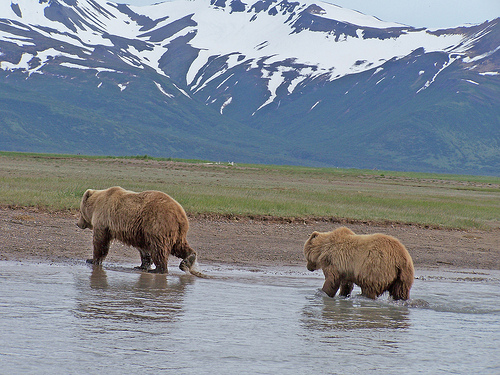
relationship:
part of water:
[232, 309, 331, 363] [2, 257, 496, 374]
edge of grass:
[186, 208, 463, 233] [0, 149, 499, 233]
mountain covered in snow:
[2, 2, 499, 162] [250, 67, 294, 119]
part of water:
[213, 310, 260, 351] [96, 273, 331, 364]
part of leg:
[151, 245, 167, 257] [150, 240, 169, 275]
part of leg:
[151, 245, 167, 257] [172, 234, 197, 271]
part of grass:
[300, 168, 370, 221] [0, 149, 499, 233]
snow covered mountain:
[201, 18, 286, 55] [84, 23, 431, 123]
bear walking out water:
[281, 182, 427, 309] [194, 316, 394, 354]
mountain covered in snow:
[2, 2, 499, 162] [1, 0, 468, 83]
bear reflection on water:
[72, 268, 193, 338] [2, 257, 496, 374]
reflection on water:
[300, 291, 411, 339] [2, 257, 496, 374]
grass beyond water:
[240, 194, 454, 221] [96, 190, 384, 353]